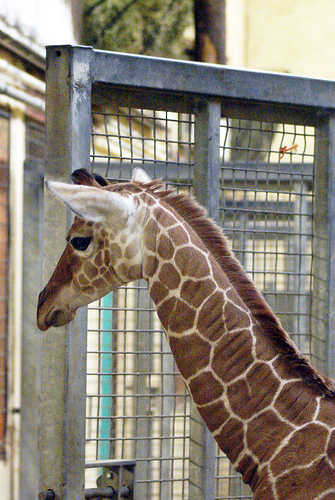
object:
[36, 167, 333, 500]
giraffe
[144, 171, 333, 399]
hair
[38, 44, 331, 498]
gate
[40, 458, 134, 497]
lock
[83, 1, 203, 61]
trees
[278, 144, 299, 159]
string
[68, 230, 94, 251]
eye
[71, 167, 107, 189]
horn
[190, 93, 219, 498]
bar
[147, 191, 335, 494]
neck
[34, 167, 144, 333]
head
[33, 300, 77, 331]
mouth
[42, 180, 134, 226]
ear